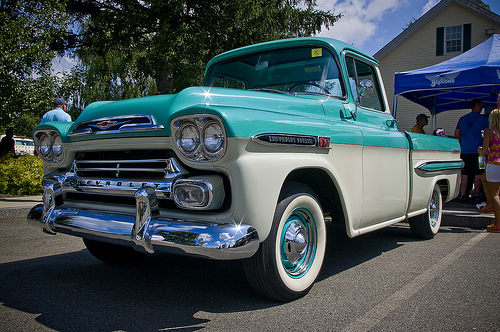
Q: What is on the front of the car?
A: A grill.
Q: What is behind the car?
A: A tent.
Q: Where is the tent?
A: Behind the car.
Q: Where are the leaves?
A: On the trees.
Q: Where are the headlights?
A: On the front of the car.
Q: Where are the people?
A: Under the tent.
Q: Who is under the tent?
A: The people.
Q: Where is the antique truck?
A: In the driveway.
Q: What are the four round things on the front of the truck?
A: Headlights.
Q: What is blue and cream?
A: Antique truck.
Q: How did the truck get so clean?
A: Washed.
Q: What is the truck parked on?
A: Pavement.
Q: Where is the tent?
A: Behind the truck.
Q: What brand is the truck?
A: Chevrolet.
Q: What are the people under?
A: Canopy.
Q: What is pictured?
A: An old truck.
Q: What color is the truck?
A: Teal and white.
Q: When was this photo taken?
A: During the day.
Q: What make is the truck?
A: A chevrolet.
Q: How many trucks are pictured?
A: Just 1.